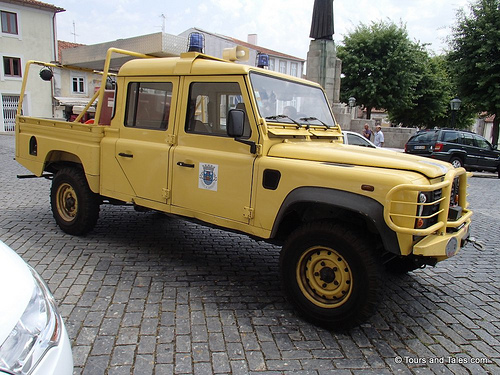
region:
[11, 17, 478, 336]
this is a truck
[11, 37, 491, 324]
a truck painted yellow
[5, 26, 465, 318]
a yellow colored truck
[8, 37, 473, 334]
a yellow painted truck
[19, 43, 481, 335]
a painted yellow truck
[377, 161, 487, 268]
the bumper guard is yellow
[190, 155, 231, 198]
a decal with a shield emblem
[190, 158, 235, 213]
a white square decal with an emblem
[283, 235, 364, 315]
the wheel is yellow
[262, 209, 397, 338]
the tire is black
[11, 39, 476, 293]
yellow truck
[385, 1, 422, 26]
white clouds in blue sky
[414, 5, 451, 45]
white clouds in blue sky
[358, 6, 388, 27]
white clouds in blue sky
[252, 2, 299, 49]
white clouds in blue sky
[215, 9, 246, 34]
white clouds in blue sky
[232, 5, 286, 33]
white clouds in blue sky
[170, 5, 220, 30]
white clouds in blue sky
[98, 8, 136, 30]
white clouds in blue sky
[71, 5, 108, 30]
white clouds in blue sky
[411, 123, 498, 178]
a green jeep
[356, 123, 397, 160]
people standing behind the jeep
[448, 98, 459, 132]
a light post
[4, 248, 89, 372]
a white car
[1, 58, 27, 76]
a window on the building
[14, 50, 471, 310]
a yellow truck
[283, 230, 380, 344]
a tire on the truck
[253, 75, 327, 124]
a windshield on the truck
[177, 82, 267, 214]
the door on the truck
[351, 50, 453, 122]
trees behind the lights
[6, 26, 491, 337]
a yellow vehicle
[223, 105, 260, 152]
a side mirror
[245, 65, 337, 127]
a windshield of the vehicle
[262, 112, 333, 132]
wipers of the vehicle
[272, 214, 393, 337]
front wheel of the vehicle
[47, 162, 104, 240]
a rear wheel of the vehicle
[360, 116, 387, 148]
people in the background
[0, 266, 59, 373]
head light of the car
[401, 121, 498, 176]
a black vehicle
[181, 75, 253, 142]
a window of the vehicle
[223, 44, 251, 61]
Speaker system on top of yellow truck.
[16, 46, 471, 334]
Yellow truck is parked.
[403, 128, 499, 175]
Black SUV parked behind yellow truck.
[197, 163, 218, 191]
White logo on yellow truck door.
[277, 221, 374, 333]
Front wheel on yellow truck.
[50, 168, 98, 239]
Back wheel on yellow truck.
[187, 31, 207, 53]
Left blue light on top of yellow truck.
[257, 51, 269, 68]
Right blue light on top of yellow truck.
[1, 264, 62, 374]
Headlight of white car.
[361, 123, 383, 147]
Two people standing in the background.